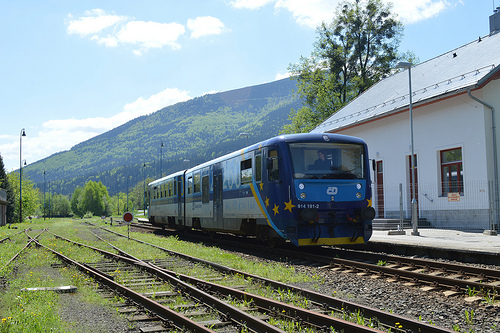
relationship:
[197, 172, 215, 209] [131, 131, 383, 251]
window on vehicle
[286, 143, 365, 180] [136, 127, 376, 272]
window on vehicle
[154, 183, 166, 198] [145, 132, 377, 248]
window on vehicle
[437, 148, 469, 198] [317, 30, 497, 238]
window on building